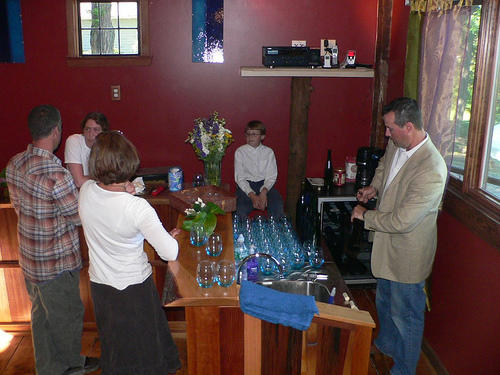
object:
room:
[2, 1, 499, 375]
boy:
[233, 120, 280, 222]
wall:
[1, 0, 385, 144]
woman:
[78, 132, 179, 374]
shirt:
[78, 179, 181, 291]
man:
[6, 102, 88, 353]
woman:
[64, 111, 108, 188]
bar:
[164, 177, 375, 340]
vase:
[201, 159, 224, 191]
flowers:
[211, 121, 221, 136]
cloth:
[236, 279, 318, 331]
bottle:
[350, 192, 364, 252]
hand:
[350, 203, 367, 222]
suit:
[365, 132, 449, 277]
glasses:
[194, 258, 221, 287]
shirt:
[234, 144, 280, 193]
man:
[351, 98, 448, 339]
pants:
[374, 273, 427, 372]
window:
[79, 2, 138, 54]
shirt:
[5, 144, 81, 286]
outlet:
[110, 84, 122, 103]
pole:
[287, 76, 312, 234]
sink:
[246, 275, 336, 301]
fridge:
[303, 177, 380, 286]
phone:
[331, 44, 341, 66]